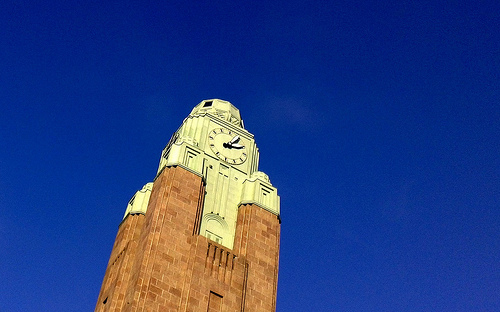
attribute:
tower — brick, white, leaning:
[96, 98, 283, 309]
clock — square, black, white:
[207, 124, 249, 165]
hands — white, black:
[224, 136, 244, 151]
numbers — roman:
[208, 126, 246, 166]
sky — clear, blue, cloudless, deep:
[1, 1, 500, 311]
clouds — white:
[265, 94, 309, 123]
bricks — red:
[93, 166, 281, 309]